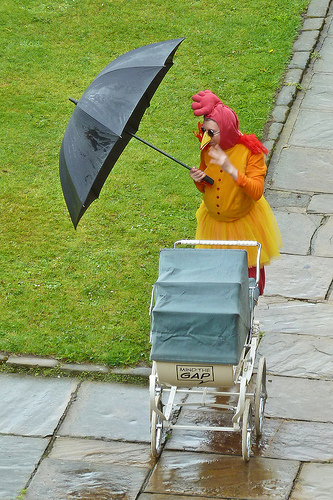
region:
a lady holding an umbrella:
[136, 94, 279, 274]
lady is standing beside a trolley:
[171, 134, 312, 452]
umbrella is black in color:
[65, 64, 167, 153]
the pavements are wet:
[43, 416, 157, 495]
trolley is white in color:
[163, 368, 251, 412]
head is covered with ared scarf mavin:
[197, 82, 258, 142]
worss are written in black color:
[172, 360, 238, 392]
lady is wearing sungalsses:
[201, 124, 263, 212]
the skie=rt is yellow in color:
[208, 217, 276, 254]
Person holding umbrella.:
[83, 125, 201, 170]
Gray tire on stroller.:
[231, 415, 268, 491]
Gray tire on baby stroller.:
[146, 405, 177, 462]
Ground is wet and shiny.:
[56, 434, 126, 477]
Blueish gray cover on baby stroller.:
[162, 250, 245, 336]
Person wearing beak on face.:
[192, 128, 208, 151]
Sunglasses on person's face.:
[196, 127, 221, 145]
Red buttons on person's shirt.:
[215, 174, 229, 220]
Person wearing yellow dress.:
[215, 197, 283, 258]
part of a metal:
[146, 441, 168, 470]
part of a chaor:
[197, 370, 227, 418]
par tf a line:
[185, 430, 208, 473]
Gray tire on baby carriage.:
[237, 422, 269, 455]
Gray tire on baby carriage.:
[132, 417, 173, 454]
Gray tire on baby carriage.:
[253, 373, 280, 442]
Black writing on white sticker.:
[174, 366, 217, 382]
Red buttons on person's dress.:
[206, 171, 224, 236]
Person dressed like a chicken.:
[199, 93, 230, 138]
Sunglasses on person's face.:
[198, 123, 221, 141]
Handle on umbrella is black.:
[184, 169, 217, 191]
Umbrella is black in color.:
[59, 70, 139, 145]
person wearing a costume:
[180, 82, 285, 298]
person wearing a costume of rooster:
[185, 82, 282, 286]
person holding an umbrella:
[39, 28, 279, 236]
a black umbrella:
[47, 26, 187, 239]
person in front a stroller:
[129, 70, 295, 467]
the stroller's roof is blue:
[139, 235, 277, 466]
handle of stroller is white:
[171, 232, 263, 248]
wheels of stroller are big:
[141, 359, 276, 466]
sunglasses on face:
[194, 121, 222, 138]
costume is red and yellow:
[180, 84, 283, 304]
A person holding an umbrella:
[49, 28, 279, 237]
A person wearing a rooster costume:
[181, 74, 284, 299]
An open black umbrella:
[47, 24, 215, 230]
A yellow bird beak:
[188, 121, 214, 153]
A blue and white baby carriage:
[136, 226, 278, 466]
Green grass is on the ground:
[0, 0, 311, 373]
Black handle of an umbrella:
[198, 166, 216, 187]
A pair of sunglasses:
[188, 113, 218, 135]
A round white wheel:
[244, 346, 277, 446]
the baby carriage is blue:
[132, 228, 274, 465]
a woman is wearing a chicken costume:
[172, 86, 279, 306]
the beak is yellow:
[191, 130, 212, 155]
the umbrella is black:
[41, 47, 195, 208]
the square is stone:
[60, 375, 176, 453]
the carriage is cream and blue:
[122, 229, 275, 470]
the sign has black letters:
[171, 363, 229, 394]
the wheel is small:
[232, 402, 263, 468]